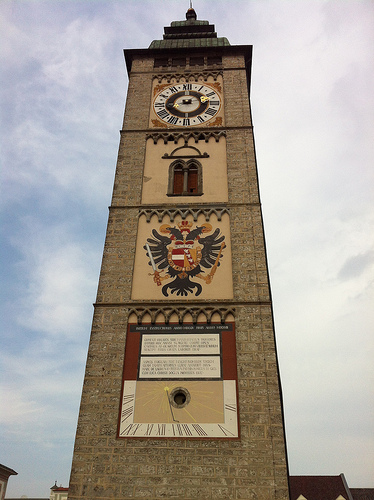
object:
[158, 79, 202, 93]
numbers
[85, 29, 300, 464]
tower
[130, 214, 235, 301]
mural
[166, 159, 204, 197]
windows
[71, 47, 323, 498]
tower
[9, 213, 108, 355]
cloud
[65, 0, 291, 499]
tower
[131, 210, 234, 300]
bird diety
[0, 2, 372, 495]
sky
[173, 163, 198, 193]
double door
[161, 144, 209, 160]
arch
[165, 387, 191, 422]
image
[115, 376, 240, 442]
plaque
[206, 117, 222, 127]
creature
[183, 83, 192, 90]
roman numeral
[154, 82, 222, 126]
clock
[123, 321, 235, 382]
plaque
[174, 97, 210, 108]
hands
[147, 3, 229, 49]
building top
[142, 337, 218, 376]
words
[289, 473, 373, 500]
rooftop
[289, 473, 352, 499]
building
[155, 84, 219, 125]
roman numerals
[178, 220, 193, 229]
crown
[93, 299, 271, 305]
ridge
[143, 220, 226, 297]
shield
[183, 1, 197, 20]
peak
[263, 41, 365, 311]
clouds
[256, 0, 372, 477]
clouds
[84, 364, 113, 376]
stone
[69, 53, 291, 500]
wall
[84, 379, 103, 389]
stone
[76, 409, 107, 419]
stone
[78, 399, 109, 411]
stone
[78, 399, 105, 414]
stone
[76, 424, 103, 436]
stone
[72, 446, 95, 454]
stone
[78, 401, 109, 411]
stone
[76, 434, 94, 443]
stone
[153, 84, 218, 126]
face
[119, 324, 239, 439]
sign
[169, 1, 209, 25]
steeple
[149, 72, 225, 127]
trim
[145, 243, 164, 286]
sword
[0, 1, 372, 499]
scene